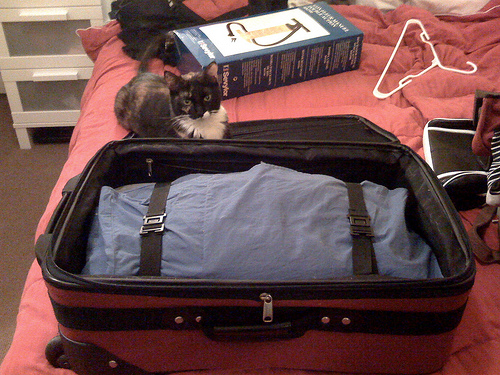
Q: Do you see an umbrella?
A: No, there are no umbrellas.